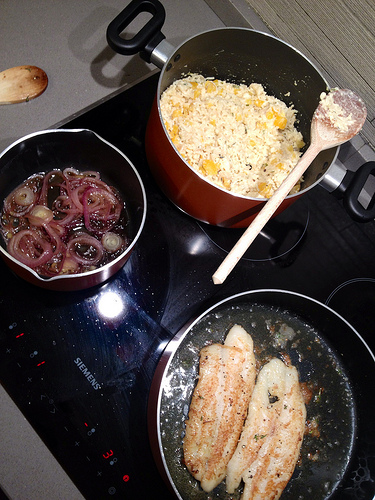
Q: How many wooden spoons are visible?
A: 2.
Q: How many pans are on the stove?
A: 3.